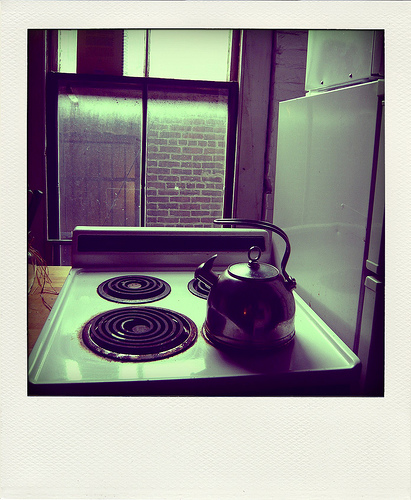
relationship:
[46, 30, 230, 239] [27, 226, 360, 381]
window behind stove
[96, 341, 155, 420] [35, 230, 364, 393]
rust around side of stove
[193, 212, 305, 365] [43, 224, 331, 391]
kettle on stove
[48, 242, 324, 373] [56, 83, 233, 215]
stove top sit in front of a window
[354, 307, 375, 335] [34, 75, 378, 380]
fridge next to stove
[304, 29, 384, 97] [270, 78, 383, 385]
appliance sits on fridge